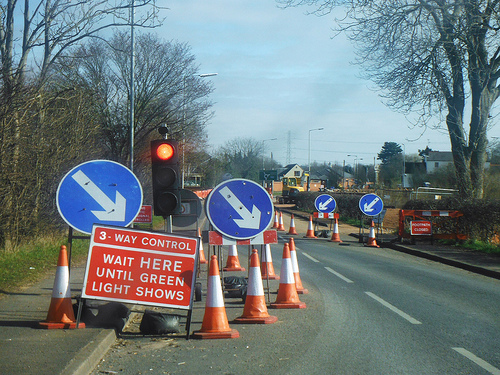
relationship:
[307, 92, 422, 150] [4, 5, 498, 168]
clouds in sky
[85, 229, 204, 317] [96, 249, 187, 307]
sign has writing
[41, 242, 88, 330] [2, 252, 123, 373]
cone on sidewalk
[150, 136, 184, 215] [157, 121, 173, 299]
street light on a pole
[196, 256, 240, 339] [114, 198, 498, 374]
cone on street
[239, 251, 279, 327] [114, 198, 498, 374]
cone on street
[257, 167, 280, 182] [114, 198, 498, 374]
traffic sign on street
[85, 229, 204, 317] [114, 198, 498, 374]
sign on street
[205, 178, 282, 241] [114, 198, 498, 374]
sign on street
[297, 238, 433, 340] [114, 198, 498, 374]
line on street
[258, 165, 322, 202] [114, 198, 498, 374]
house off street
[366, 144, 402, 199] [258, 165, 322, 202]
tree by house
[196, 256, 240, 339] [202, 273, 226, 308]
cone has stripe